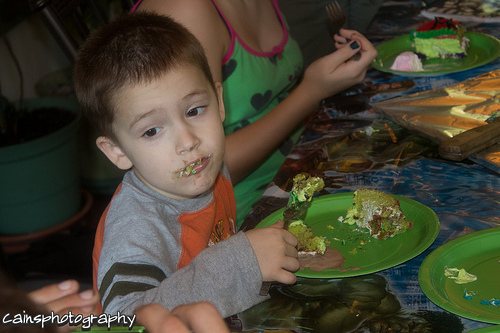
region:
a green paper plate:
[420, 224, 499, 324]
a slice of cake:
[410, 16, 474, 59]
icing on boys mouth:
[173, 153, 216, 179]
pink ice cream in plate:
[387, 48, 421, 72]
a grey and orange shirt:
[92, 158, 270, 320]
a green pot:
[0, 97, 82, 235]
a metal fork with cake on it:
[255, 180, 306, 305]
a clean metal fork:
[323, 1, 350, 36]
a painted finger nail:
[347, 36, 359, 51]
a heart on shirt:
[250, 85, 274, 114]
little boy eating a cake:
[90, 32, 399, 269]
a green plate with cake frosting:
[433, 205, 498, 328]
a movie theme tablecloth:
[291, 101, 408, 181]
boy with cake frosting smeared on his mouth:
[163, 140, 233, 187]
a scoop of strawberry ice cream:
[382, 45, 423, 75]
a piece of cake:
[408, 9, 473, 63]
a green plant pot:
[5, 92, 87, 255]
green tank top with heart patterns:
[218, 54, 329, 179]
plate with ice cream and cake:
[371, 11, 498, 71]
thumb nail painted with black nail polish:
[343, 33, 367, 57]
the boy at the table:
[55, 15, 305, 328]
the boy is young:
[68, 9, 292, 331]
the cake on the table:
[372, 10, 496, 107]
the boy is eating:
[66, 26, 311, 331]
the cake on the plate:
[241, 182, 446, 289]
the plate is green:
[236, 192, 446, 295]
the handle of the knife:
[419, 125, 499, 173]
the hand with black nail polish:
[272, 21, 412, 112]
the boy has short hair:
[60, 11, 232, 201]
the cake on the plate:
[377, 26, 491, 95]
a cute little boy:
[29, 31, 266, 226]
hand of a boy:
[224, 212, 295, 284]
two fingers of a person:
[140, 294, 235, 330]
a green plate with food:
[276, 185, 441, 280]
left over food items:
[282, 178, 438, 293]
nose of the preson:
[178, 130, 201, 148]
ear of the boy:
[95, 117, 155, 191]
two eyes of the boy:
[128, 97, 220, 141]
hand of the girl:
[308, 27, 403, 96]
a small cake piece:
[378, 30, 490, 76]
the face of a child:
[137, 99, 220, 182]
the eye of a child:
[136, 120, 160, 143]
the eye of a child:
[181, 98, 213, 120]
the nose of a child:
[176, 125, 199, 157]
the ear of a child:
[91, 130, 136, 177]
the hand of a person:
[308, 28, 375, 98]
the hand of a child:
[252, 225, 307, 289]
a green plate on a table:
[336, 180, 439, 289]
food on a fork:
[278, 172, 323, 232]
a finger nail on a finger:
[53, 274, 80, 294]